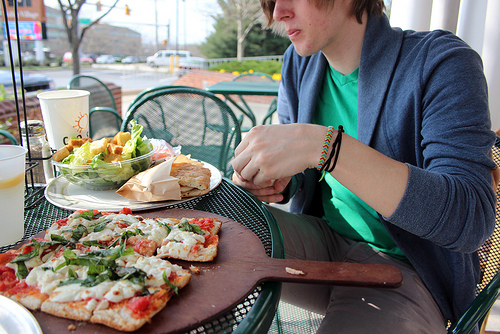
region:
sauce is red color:
[117, 295, 169, 317]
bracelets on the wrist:
[312, 122, 354, 177]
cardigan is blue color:
[367, 51, 479, 287]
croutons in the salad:
[59, 135, 161, 179]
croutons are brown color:
[92, 137, 131, 159]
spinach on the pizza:
[77, 250, 135, 284]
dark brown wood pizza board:
[11, 205, 403, 332]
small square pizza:
[0, 206, 222, 329]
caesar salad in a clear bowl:
[48, 116, 158, 189]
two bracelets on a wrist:
[315, 119, 347, 183]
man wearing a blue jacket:
[201, 0, 493, 332]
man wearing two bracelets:
[178, 0, 498, 330]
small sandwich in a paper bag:
[112, 151, 211, 206]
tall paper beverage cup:
[32, 88, 92, 185]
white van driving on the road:
[145, 46, 192, 69]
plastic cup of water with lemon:
[0, 143, 27, 248]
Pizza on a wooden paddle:
[0, 205, 399, 332]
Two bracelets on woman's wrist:
[317, 122, 342, 182]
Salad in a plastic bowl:
[54, 119, 176, 188]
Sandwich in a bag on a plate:
[122, 153, 217, 202]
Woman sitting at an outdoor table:
[233, 0, 498, 332]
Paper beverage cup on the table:
[36, 85, 89, 180]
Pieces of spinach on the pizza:
[69, 246, 145, 285]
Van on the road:
[144, 46, 189, 70]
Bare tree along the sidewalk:
[58, 0, 123, 83]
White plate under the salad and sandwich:
[43, 154, 225, 211]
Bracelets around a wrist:
[316, 120, 347, 188]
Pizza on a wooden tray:
[1, 199, 409, 332]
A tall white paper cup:
[35, 86, 94, 153]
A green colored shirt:
[311, 65, 414, 260]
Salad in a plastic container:
[48, 123, 160, 194]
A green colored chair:
[118, 85, 247, 177]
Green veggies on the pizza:
[12, 206, 209, 300]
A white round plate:
[42, 154, 223, 214]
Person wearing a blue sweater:
[261, 0, 498, 332]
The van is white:
[144, 46, 197, 71]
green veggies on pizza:
[46, 214, 128, 284]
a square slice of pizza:
[104, 256, 184, 320]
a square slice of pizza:
[170, 219, 226, 261]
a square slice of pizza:
[52, 253, 127, 308]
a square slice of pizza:
[25, 246, 78, 304]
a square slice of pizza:
[125, 207, 166, 259]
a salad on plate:
[57, 136, 149, 187]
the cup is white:
[43, 91, 112, 150]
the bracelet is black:
[311, 124, 368, 192]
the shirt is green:
[308, 66, 391, 244]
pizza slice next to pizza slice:
[87, 256, 190, 329]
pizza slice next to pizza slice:
[156, 216, 219, 258]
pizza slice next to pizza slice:
[110, 216, 177, 251]